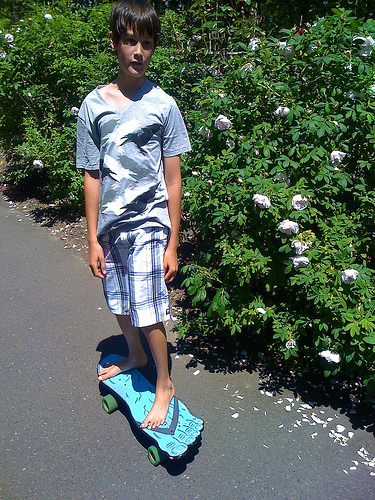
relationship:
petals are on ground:
[278, 398, 353, 452] [0, 236, 90, 496]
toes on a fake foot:
[162, 414, 204, 465] [92, 350, 207, 464]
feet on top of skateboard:
[98, 356, 173, 427] [92, 350, 207, 464]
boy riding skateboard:
[71, 0, 180, 427] [92, 350, 207, 464]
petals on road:
[278, 398, 353, 452] [0, 236, 90, 496]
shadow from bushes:
[180, 341, 277, 391] [195, 25, 372, 372]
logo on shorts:
[164, 308, 173, 317] [91, 225, 178, 326]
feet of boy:
[142, 381, 174, 432] [71, 0, 180, 427]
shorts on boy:
[91, 225, 178, 326] [71, 0, 180, 427]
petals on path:
[278, 398, 353, 452] [0, 236, 90, 496]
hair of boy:
[104, 0, 167, 36] [71, 0, 180, 427]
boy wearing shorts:
[71, 0, 180, 427] [91, 225, 178, 326]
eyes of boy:
[124, 36, 153, 49] [71, 0, 180, 427]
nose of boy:
[135, 47, 145, 59] [71, 0, 180, 427]